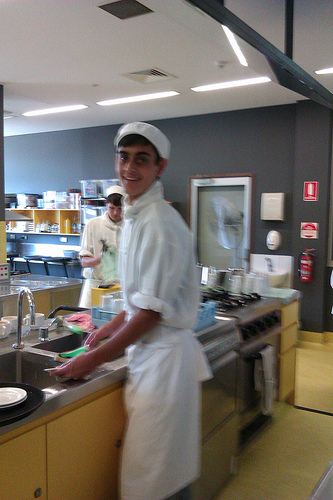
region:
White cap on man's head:
[110, 123, 173, 156]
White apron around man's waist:
[117, 332, 200, 498]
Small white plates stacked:
[1, 386, 24, 406]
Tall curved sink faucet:
[11, 287, 35, 345]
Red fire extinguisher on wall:
[298, 246, 315, 282]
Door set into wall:
[190, 176, 248, 273]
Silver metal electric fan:
[205, 196, 245, 271]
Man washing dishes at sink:
[47, 146, 203, 496]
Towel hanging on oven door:
[256, 346, 275, 418]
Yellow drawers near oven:
[283, 299, 297, 398]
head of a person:
[96, 123, 171, 202]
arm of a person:
[91, 286, 165, 372]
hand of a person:
[50, 346, 100, 381]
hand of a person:
[72, 316, 106, 358]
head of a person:
[95, 178, 126, 223]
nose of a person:
[118, 164, 142, 178]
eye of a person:
[113, 147, 131, 167]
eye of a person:
[135, 155, 147, 165]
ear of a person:
[146, 153, 174, 191]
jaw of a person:
[112, 180, 140, 200]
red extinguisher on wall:
[299, 243, 316, 289]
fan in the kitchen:
[205, 198, 251, 274]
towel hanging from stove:
[254, 346, 280, 421]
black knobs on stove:
[242, 308, 281, 343]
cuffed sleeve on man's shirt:
[135, 291, 177, 321]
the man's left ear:
[159, 158, 167, 177]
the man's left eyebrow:
[133, 150, 150, 157]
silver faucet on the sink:
[18, 287, 36, 349]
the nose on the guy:
[124, 162, 135, 173]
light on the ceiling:
[95, 87, 183, 112]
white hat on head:
[111, 112, 179, 167]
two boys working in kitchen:
[59, 112, 221, 442]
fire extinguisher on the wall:
[285, 242, 321, 290]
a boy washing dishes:
[24, 127, 219, 496]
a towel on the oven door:
[245, 340, 295, 464]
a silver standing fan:
[198, 195, 266, 296]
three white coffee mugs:
[3, 309, 55, 336]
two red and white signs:
[296, 180, 325, 249]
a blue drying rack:
[80, 285, 227, 346]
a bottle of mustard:
[59, 215, 74, 242]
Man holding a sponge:
[44, 120, 217, 499]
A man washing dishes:
[44, 117, 211, 488]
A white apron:
[114, 339, 204, 498]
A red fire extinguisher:
[298, 246, 315, 284]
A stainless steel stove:
[203, 292, 288, 433]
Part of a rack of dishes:
[88, 285, 124, 323]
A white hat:
[109, 119, 169, 158]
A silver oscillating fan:
[203, 193, 251, 281]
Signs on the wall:
[298, 177, 321, 245]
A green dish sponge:
[48, 333, 109, 367]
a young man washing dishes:
[50, 121, 210, 499]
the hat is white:
[113, 121, 169, 159]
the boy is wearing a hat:
[48, 121, 214, 498]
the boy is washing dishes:
[44, 122, 212, 498]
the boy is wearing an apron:
[52, 121, 215, 499]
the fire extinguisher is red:
[298, 247, 315, 281]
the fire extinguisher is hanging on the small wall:
[291, 100, 329, 332]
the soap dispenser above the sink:
[247, 230, 294, 290]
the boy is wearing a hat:
[80, 185, 128, 279]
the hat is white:
[105, 185, 124, 197]